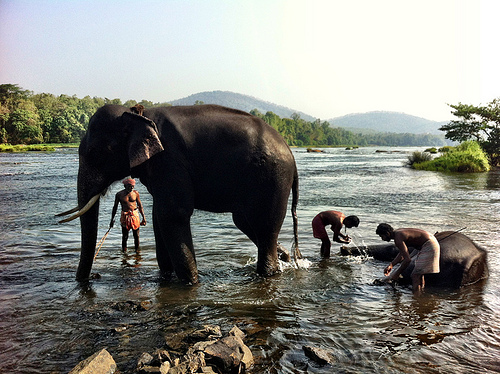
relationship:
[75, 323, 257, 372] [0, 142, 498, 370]
rocks in water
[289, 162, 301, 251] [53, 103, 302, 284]
tail of elephant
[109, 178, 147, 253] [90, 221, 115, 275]
man holding stick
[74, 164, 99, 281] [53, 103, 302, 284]
trunk of elephant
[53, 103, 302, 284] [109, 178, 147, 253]
elephant bathing with man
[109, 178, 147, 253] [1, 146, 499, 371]
man bathing in river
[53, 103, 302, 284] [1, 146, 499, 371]
elephant bathing in river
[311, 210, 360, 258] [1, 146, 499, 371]
man bathing in river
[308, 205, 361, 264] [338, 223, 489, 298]
man bathing elephant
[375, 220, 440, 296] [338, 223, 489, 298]
man bathing elephant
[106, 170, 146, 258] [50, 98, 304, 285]
man bathing elephant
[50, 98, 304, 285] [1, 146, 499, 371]
elephant in river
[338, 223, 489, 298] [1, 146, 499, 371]
elephant in river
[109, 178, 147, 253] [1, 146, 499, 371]
man wading in river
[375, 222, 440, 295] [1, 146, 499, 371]
man in river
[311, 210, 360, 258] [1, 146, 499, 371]
man in river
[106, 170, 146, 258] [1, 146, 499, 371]
man in river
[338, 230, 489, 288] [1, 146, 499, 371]
elephant in river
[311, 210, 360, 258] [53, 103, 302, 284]
man washes elephant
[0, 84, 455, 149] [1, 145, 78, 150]
trees lines line riverbank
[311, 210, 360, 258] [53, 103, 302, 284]
man splashes elephant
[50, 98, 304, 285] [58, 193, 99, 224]
elephant has tusk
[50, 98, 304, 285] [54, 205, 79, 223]
elephant has tusk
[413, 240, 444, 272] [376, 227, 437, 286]
cloth wrapped around man